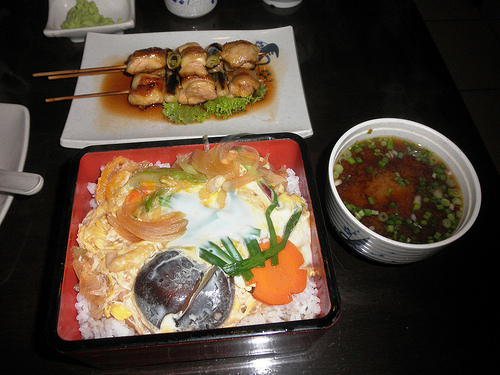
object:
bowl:
[323, 117, 482, 265]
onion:
[378, 212, 387, 222]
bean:
[261, 177, 279, 266]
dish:
[40, 132, 339, 356]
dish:
[43, 0, 136, 42]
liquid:
[181, 226, 210, 242]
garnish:
[160, 104, 210, 123]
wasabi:
[60, 0, 115, 31]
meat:
[140, 59, 153, 69]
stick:
[33, 51, 266, 78]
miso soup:
[332, 134, 465, 245]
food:
[71, 140, 321, 340]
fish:
[179, 43, 208, 63]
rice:
[295, 304, 303, 311]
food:
[128, 74, 165, 105]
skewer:
[45, 77, 269, 102]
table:
[0, 0, 498, 374]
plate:
[59, 26, 315, 149]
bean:
[199, 248, 226, 268]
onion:
[374, 149, 380, 156]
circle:
[241, 235, 308, 306]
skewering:
[49, 51, 268, 79]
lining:
[55, 140, 328, 341]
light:
[243, 358, 281, 374]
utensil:
[2, 168, 43, 198]